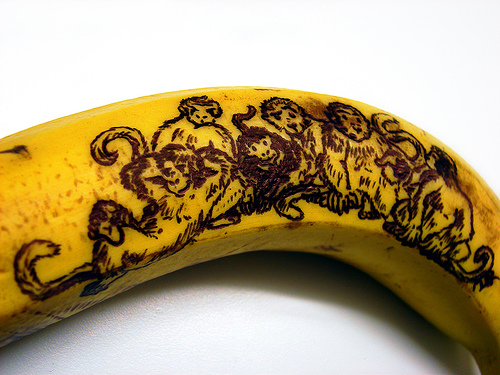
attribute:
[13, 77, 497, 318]
banana — yellow, missing tip, tail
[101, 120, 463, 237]
6 monkeys — drawn, black drawing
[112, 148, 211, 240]
monkey — on its back, black, looking left, yellow, brown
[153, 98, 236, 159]
monkey — observing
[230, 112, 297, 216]
monkey — playful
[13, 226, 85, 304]
tail — curled, dark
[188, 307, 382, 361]
plate — white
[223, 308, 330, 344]
light — reflecting on plate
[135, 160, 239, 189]
arms — behind head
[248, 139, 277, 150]
black dots — eyes